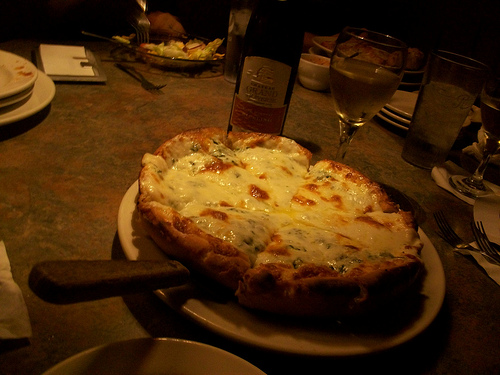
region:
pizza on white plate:
[111, 125, 441, 354]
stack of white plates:
[2, 49, 54, 127]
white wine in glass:
[322, 25, 403, 155]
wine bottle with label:
[225, 3, 307, 134]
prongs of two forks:
[434, 213, 499, 265]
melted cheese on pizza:
[156, 147, 401, 269]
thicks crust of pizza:
[246, 266, 416, 311]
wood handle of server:
[30, 252, 191, 304]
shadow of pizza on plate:
[126, 213, 159, 262]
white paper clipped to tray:
[37, 44, 102, 86]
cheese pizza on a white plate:
[136, 121, 429, 308]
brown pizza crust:
[246, 264, 426, 307]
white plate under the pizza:
[112, 175, 449, 358]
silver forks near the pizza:
[430, 203, 499, 266]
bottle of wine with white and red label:
[226, 3, 317, 143]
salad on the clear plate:
[140, 38, 224, 63]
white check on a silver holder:
[27, 40, 110, 87]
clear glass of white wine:
[323, 23, 410, 170]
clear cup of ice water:
[393, 42, 490, 172]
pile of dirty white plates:
[0, 45, 58, 127]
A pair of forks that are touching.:
[431, 205, 494, 265]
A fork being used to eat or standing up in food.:
[135, 5, 155, 50]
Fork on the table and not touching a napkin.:
[111, 56, 169, 96]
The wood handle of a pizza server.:
[29, 253, 186, 302]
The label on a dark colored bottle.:
[226, 49, 292, 141]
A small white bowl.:
[295, 51, 340, 94]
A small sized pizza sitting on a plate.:
[130, 119, 443, 326]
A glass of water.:
[403, 40, 483, 180]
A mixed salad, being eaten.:
[117, 24, 225, 79]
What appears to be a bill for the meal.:
[35, 40, 98, 88]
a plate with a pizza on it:
[112, 130, 442, 350]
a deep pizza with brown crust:
[135, 125, 420, 280]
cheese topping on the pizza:
[185, 165, 355, 225]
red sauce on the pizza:
[245, 185, 275, 201]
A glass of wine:
[323, 55, 393, 162]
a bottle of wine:
[228, 0, 304, 135]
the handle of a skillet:
[34, 255, 196, 305]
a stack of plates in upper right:
[0, 47, 57, 124]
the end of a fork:
[469, 219, 496, 269]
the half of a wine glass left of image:
[459, 87, 499, 203]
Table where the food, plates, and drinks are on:
[60, 130, 97, 170]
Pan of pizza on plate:
[133, 120, 426, 311]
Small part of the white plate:
[428, 265, 443, 292]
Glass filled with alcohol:
[333, 27, 406, 142]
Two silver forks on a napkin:
[436, 203, 499, 261]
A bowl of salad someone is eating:
[156, 31, 215, 62]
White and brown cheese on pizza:
[218, 175, 275, 217]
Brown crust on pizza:
[167, 230, 211, 267]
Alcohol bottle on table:
[227, 5, 307, 123]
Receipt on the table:
[44, 32, 101, 83]